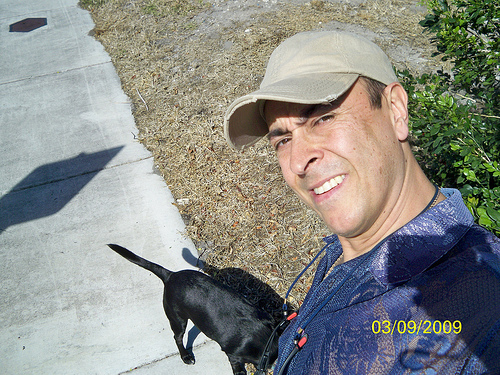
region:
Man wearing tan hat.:
[249, 50, 346, 112]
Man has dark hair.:
[346, 80, 395, 112]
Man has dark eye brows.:
[261, 126, 301, 141]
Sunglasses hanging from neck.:
[275, 294, 328, 370]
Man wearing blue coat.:
[365, 295, 409, 342]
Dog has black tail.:
[96, 234, 164, 273]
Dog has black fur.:
[168, 297, 292, 358]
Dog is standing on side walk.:
[124, 251, 255, 342]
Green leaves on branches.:
[443, 112, 499, 179]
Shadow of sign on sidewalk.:
[16, 125, 93, 220]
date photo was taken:
[370, 315, 461, 340]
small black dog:
[106, 241, 281, 368]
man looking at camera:
[222, 27, 497, 374]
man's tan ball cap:
[221, 26, 403, 158]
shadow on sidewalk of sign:
[3, 143, 122, 234]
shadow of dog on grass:
[181, 245, 297, 325]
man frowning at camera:
[218, 27, 415, 247]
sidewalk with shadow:
[7, 2, 201, 372]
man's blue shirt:
[276, 188, 496, 373]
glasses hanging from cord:
[256, 308, 307, 373]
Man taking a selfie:
[207, 34, 491, 327]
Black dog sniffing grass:
[97, 246, 287, 372]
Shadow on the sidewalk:
[20, 131, 133, 241]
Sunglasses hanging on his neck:
[259, 230, 321, 369]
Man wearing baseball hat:
[211, 7, 413, 138]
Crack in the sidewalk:
[21, 59, 124, 86]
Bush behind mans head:
[407, 5, 495, 168]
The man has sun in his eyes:
[255, 105, 370, 242]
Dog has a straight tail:
[90, 231, 182, 283]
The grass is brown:
[149, 71, 239, 206]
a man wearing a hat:
[213, 31, 405, 233]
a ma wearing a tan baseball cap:
[166, 23, 416, 176]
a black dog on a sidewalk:
[148, 265, 287, 360]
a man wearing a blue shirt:
[271, 67, 441, 347]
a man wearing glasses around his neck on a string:
[248, 154, 452, 374]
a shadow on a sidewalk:
[0, 101, 139, 265]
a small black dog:
[120, 240, 289, 374]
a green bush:
[406, 2, 494, 187]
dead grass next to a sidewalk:
[73, 18, 230, 266]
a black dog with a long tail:
[66, 232, 296, 359]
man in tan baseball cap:
[211, 28, 434, 248]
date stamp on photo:
[365, 314, 467, 344]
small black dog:
[102, 236, 292, 373]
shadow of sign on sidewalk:
[10, 134, 124, 222]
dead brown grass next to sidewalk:
[139, 34, 239, 215]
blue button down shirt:
[261, 186, 481, 373]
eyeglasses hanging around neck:
[240, 242, 324, 370]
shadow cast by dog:
[180, 244, 295, 319]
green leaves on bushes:
[419, 25, 472, 168]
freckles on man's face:
[352, 86, 376, 123]